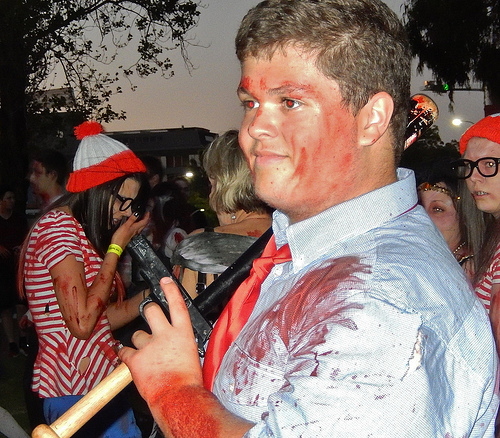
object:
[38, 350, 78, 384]
stripe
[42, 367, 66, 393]
stripe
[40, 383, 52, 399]
stripe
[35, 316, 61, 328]
stripe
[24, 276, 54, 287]
stripe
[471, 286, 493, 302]
stripe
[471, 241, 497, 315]
shirt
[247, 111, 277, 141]
nose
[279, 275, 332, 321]
blood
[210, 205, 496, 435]
shirt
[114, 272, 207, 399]
hand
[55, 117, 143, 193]
hat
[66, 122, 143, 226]
head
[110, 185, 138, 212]
glasses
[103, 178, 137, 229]
face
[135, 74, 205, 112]
sky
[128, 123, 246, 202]
land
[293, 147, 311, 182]
blood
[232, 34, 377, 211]
face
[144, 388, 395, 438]
arms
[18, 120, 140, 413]
woman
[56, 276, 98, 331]
blood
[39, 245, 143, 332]
arms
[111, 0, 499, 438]
man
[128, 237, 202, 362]
gun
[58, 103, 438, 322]
bat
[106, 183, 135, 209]
eyeglasses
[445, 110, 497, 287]
woman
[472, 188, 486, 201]
teeth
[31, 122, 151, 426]
girl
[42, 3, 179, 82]
branches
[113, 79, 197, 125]
sunset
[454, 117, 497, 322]
girl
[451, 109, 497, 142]
beanie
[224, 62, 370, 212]
red paint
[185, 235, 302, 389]
red tie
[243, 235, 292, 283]
loose knot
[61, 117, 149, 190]
cap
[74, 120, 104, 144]
pom pom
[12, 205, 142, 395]
striped shirt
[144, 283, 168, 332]
finger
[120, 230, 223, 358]
hand gun